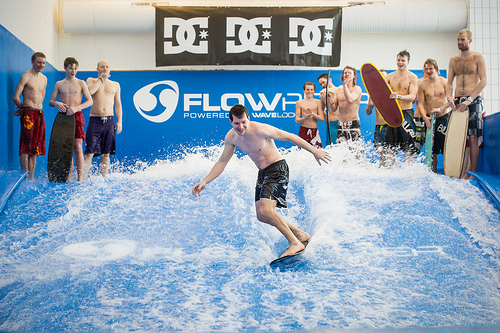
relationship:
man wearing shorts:
[47, 56, 96, 186] [76, 110, 89, 142]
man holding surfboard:
[47, 56, 96, 186] [46, 109, 83, 181]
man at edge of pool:
[47, 56, 96, 186] [2, 143, 498, 332]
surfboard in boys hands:
[43, 108, 75, 205] [43, 53, 95, 183]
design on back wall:
[126, 81, 198, 138] [56, 52, 433, 154]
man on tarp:
[191, 106, 332, 255] [0, 171, 15, 188]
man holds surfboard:
[47, 56, 96, 186] [42, 102, 77, 179]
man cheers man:
[191, 104, 332, 259] [191, 104, 332, 259]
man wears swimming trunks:
[191, 104, 332, 259] [300, 125, 323, 147]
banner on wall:
[155, 4, 342, 69] [54, 1, 466, 156]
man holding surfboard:
[191, 104, 332, 259] [421, 87, 498, 189]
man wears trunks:
[191, 104, 332, 259] [86, 115, 116, 155]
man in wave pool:
[191, 106, 332, 255] [0, 137, 499, 329]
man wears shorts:
[191, 104, 332, 259] [253, 152, 291, 208]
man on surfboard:
[191, 106, 332, 255] [267, 234, 310, 266]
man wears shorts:
[13, 37, 49, 182] [16, 100, 48, 160]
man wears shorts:
[47, 56, 96, 186] [68, 104, 89, 153]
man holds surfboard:
[47, 56, 96, 186] [46, 107, 77, 184]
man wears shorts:
[47, 56, 96, 186] [83, 110, 121, 160]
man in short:
[47, 56, 96, 186] [17, 101, 52, 158]